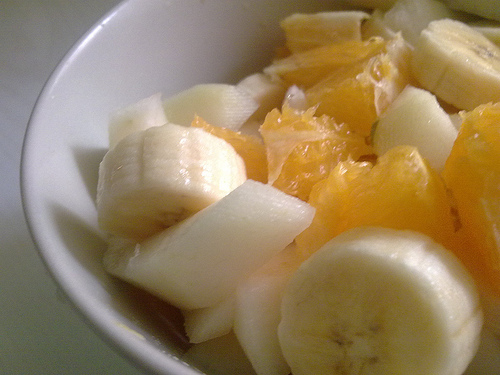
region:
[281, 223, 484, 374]
big slice of banana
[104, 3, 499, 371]
bowl of fruit slices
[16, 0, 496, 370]
white bowl with fruit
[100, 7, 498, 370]
orange slices mixed with bananas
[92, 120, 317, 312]
banana slice on top of melon slice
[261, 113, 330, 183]
skin of an orange slice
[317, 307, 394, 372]
middle of banana slice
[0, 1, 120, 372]
white table under bowl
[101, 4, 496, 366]
white and orange fruit in bowl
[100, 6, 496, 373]
peeled and sliced fruit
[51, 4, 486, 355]
fruit salad in a bowl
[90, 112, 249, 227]
banana in the fruit salad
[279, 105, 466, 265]
orange in the salad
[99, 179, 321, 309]
melon in the salad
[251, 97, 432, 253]
the orange is light orange in color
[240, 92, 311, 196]
there is skin on the orange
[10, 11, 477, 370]
the bowl is white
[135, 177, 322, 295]
the melon is white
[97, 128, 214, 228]
the banana is mostly white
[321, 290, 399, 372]
the center of the banana is brown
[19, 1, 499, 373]
a bowl of fruit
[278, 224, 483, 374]
a slice of banana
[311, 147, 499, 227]
an orange slice in the bowl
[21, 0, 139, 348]
a white porcelain bowl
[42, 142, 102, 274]
a shadow formed from the angle of the light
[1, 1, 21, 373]
a grey table or wall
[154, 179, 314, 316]
a slice of a pair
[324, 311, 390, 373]
the black center spine of the babnana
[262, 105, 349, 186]
a slice of grape fruit in the bowl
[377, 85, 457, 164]
an apple slice in the bowl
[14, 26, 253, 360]
the bowl is white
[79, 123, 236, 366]
the bowl is white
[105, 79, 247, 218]
Banana in the bowl.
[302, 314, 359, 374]
Dark part of the banana.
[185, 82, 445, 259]
Oranges in the bowl.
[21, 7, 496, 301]
Oranges and bananas in the bowl.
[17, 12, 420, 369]
White bowl with fruit in it.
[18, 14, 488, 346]
Bowl on a table.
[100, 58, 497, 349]
Different fruits in the bowl.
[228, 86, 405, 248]
Orange colored oranges in the bowl.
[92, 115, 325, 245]
Light color bananas.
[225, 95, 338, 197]
Part of an orange.